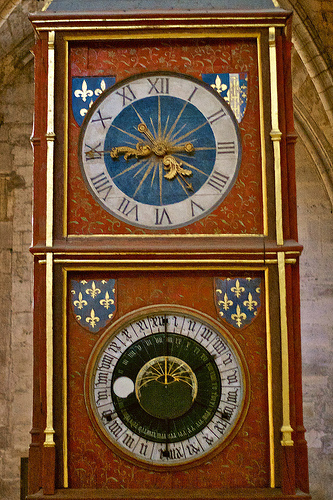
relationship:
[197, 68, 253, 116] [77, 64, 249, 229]
shield on clock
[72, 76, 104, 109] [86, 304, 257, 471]
arms on clock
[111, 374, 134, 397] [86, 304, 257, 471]
moon on clock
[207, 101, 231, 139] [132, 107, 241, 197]
numeral on clock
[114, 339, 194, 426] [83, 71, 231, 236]
center on clock